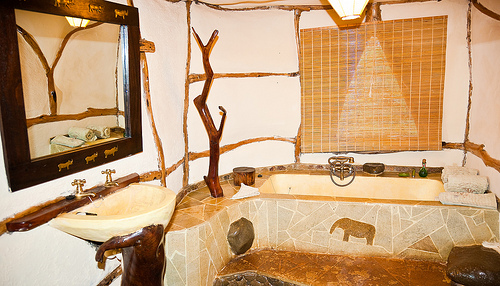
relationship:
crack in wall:
[461, 0, 477, 167] [16, 8, 495, 207]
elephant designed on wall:
[318, 217, 386, 244] [16, 8, 495, 207]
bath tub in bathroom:
[246, 163, 463, 252] [16, 8, 495, 207]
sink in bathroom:
[53, 184, 181, 243] [3, 5, 498, 283]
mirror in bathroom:
[8, 4, 141, 187] [3, 5, 498, 283]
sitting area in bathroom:
[427, 230, 499, 278] [3, 5, 498, 283]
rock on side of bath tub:
[221, 216, 254, 257] [246, 163, 463, 252]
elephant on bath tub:
[318, 217, 386, 244] [246, 163, 463, 252]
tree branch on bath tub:
[190, 20, 231, 201] [246, 163, 463, 252]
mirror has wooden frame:
[8, 4, 141, 187] [3, 140, 145, 202]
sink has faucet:
[53, 184, 181, 243] [72, 171, 97, 202]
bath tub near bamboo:
[246, 163, 463, 252] [296, 9, 454, 164]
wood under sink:
[92, 221, 168, 282] [53, 184, 181, 243]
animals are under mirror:
[52, 142, 121, 171] [8, 4, 141, 187]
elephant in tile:
[318, 217, 386, 244] [294, 209, 466, 249]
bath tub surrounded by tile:
[246, 163, 463, 252] [294, 209, 466, 249]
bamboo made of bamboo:
[300, 14, 447, 154] [296, 9, 454, 164]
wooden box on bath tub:
[226, 162, 258, 188] [246, 163, 463, 252]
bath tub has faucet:
[246, 163, 463, 252] [326, 154, 361, 182]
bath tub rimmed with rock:
[246, 163, 463, 252] [221, 216, 254, 257]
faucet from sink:
[72, 171, 97, 202] [53, 184, 181, 243]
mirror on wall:
[8, 4, 141, 187] [16, 8, 495, 207]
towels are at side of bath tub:
[438, 162, 499, 216] [246, 163, 463, 252]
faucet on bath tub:
[326, 154, 361, 182] [246, 163, 463, 252]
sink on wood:
[53, 184, 181, 243] [92, 221, 168, 282]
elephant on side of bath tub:
[318, 217, 386, 244] [246, 163, 463, 252]